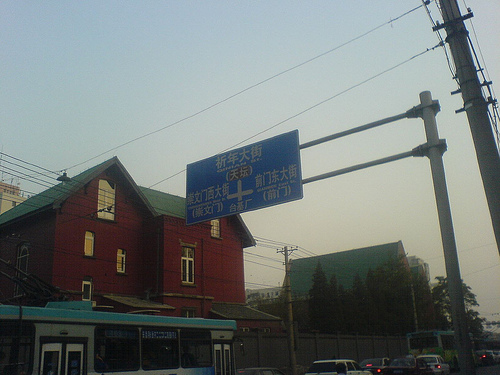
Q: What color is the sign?
A: Blue.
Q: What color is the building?
A: Red.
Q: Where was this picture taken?
A: China.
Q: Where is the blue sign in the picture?
A: Center.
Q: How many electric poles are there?
A: Two.